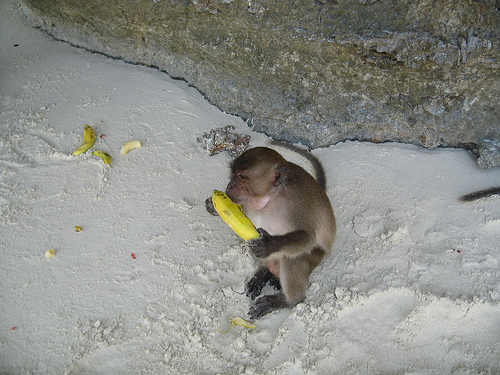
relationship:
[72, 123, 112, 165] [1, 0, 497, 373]
peel on ground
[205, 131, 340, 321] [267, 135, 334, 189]
monkey has tail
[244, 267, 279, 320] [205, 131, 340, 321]
claws on monkey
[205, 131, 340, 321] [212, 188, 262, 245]
monkey eating banana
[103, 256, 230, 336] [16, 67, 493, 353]
footprints no snow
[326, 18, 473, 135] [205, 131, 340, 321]
rock on side monkey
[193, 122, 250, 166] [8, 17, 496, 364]
object on snow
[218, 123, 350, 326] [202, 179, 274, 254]
monkey holding banana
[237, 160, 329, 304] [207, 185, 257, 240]
monkey eating banana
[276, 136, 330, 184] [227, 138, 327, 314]
tail on monkey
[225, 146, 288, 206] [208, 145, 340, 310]
head on monkey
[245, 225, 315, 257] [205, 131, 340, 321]
arm on monkey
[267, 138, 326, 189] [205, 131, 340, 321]
tail on monkey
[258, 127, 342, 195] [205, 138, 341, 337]
tail on monkey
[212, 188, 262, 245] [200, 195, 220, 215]
banana in hand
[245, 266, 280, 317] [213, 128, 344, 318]
feet on monkey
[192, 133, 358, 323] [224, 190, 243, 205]
monkey on mouth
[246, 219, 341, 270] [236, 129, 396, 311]
arm of monkey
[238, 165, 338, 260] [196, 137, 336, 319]
body of monkey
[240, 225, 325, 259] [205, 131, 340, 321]
hand of monkey